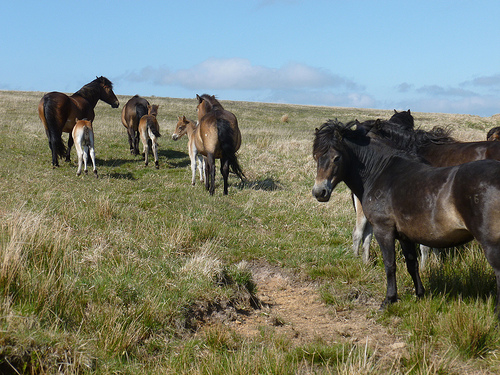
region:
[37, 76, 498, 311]
a herd of horses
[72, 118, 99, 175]
the horse is young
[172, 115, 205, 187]
the horse is small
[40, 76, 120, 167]
the horse is brown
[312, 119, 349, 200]
horse looking at camera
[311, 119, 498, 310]
horse is dark brown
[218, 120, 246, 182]
the tail is black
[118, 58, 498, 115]
some clouds far away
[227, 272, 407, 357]
dirt on the ground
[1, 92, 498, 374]
grass all over the area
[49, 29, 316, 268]
horses in a field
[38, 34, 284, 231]
horses standing in a field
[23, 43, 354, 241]
brown horses standing in a field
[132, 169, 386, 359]
a field of grass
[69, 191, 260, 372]
a field of green grass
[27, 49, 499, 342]
these are horses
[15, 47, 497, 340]
a pack of wild horses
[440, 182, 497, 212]
the horse is branded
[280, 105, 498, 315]
this horse has a black and brown hide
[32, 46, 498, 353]
the horses are on a hill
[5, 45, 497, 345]
the horses are in a field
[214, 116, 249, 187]
this is a horse's black tail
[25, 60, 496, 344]
the horses are on an incline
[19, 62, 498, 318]
Herd of wild horses on the mountainside.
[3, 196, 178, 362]
Ground covered in tall dry grass.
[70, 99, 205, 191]
Three young colts.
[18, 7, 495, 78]
Pretty light blue sky filled with few clouds.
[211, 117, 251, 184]
Long black tail on the horse.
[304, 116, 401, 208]
Horse with a beautiful black mane.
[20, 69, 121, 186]
Tall dark brown horse with it's young colt.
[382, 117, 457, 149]
Horse's mane blowing in the wind.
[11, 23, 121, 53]
clear light blue sky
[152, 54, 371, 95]
white puffy clouds in the light blue sky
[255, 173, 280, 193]
shadow of the horse on the side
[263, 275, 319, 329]
patch of ground without green grass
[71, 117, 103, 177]
small light brown and white horse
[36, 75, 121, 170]
black and brown horse with smaller horse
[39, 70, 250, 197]
three adult horses with three baby horses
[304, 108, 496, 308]
herd of adult and baby horses standing together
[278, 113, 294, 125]
lone pant of brown and golden grass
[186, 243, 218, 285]
patch of white grass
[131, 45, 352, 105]
The sky has white clouds.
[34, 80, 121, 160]
A brown horse in the field.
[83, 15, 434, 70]
The sky is clear and blue.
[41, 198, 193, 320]
The grass is green and brown.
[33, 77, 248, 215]
Horses in the grassy field.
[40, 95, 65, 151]
The tail on the horse is long and black.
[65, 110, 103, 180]
The small horse by the big horse.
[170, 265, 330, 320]
A brown patch in the grass.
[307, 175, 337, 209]
The nose of the horse.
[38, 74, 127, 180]
horse on dead grass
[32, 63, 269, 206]
horses on dead grass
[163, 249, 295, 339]
horse dung on muddy grass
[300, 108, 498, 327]
horse on dead grass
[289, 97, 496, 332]
horse on dead grass looking at camera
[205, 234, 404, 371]
dead patch of grass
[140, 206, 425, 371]
dead patch of grass by green grass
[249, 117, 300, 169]
dead patch of grass by green grass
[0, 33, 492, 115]
A cloudy sky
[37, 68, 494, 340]
The animals on the grass